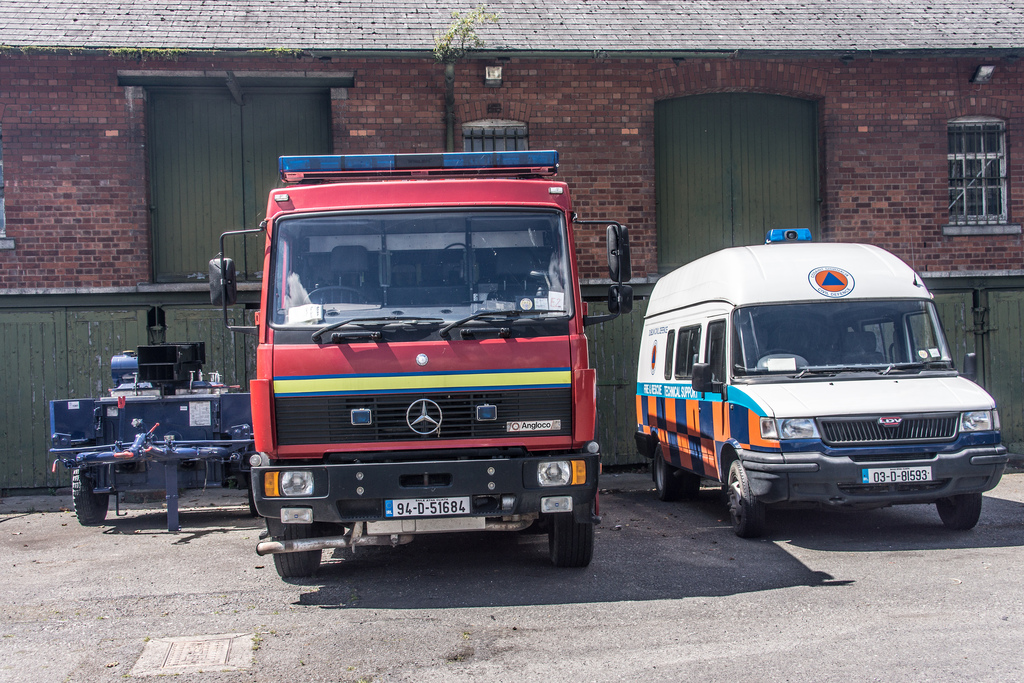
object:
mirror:
[607, 225, 634, 281]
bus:
[208, 149, 635, 579]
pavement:
[0, 471, 1024, 683]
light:
[280, 472, 315, 497]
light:
[265, 472, 281, 497]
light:
[537, 460, 572, 486]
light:
[540, 496, 572, 514]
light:
[280, 508, 313, 525]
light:
[350, 408, 370, 425]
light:
[476, 403, 496, 421]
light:
[775, 418, 822, 440]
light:
[961, 410, 993, 431]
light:
[785, 230, 799, 241]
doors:
[652, 91, 824, 277]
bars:
[948, 117, 1011, 227]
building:
[0, 0, 1024, 494]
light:
[485, 66, 502, 80]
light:
[277, 149, 557, 173]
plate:
[384, 497, 471, 518]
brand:
[406, 399, 442, 435]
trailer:
[47, 303, 271, 532]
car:
[632, 229, 1012, 543]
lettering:
[397, 500, 465, 515]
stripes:
[635, 381, 780, 482]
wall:
[0, 48, 1024, 297]